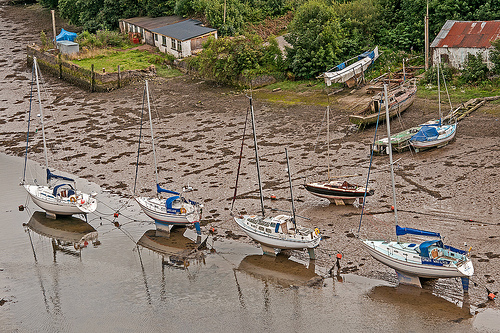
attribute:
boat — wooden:
[363, 77, 422, 126]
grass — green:
[84, 40, 152, 75]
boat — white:
[321, 44, 379, 94]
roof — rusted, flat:
[435, 13, 500, 51]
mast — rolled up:
[397, 225, 449, 240]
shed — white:
[124, 11, 220, 62]